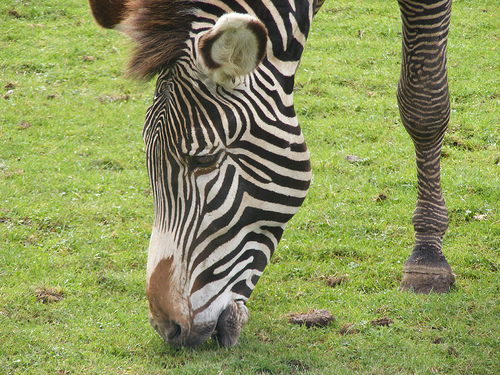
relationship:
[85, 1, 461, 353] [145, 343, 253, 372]
zebra eating grass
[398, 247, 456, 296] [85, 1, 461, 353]
hoof on a zebra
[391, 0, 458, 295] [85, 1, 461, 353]
leg of a zebra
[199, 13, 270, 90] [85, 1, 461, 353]
ear on zebra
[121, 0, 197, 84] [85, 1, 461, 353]
mane on zebra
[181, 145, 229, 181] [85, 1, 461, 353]
eye on zebra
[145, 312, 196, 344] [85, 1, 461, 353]
nose on zebra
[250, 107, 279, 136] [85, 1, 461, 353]
fur on zebra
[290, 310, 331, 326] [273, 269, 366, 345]
dirt of grass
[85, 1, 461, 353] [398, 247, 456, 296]
zebra has hoof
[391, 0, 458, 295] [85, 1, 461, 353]
leg of zebra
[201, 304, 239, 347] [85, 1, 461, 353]
mouth of zebra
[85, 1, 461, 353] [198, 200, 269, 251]
zebra has stripes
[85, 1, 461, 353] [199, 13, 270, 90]
zebra has ear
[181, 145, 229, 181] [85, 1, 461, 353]
eye of zebra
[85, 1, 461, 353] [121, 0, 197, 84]
zebra has mane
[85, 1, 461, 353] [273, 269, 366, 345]
zebra of grass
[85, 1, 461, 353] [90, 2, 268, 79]
zebra has ears